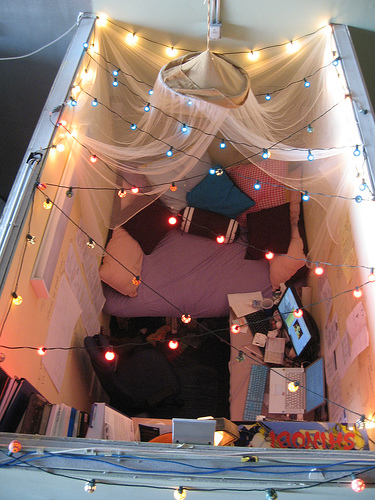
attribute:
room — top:
[17, 221, 337, 477]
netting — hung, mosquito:
[63, 137, 338, 198]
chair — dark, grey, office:
[78, 331, 183, 405]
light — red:
[130, 184, 145, 197]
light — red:
[94, 349, 133, 366]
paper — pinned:
[339, 251, 359, 284]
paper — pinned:
[344, 302, 372, 365]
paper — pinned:
[314, 280, 333, 326]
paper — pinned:
[322, 312, 338, 359]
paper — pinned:
[333, 332, 350, 380]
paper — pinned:
[324, 345, 344, 384]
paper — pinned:
[325, 377, 342, 416]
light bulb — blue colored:
[299, 190, 310, 201]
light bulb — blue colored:
[249, 175, 272, 198]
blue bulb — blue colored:
[218, 136, 232, 150]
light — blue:
[261, 89, 274, 103]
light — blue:
[90, 98, 99, 108]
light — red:
[264, 249, 275, 261]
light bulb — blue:
[249, 176, 268, 199]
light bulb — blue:
[204, 162, 221, 181]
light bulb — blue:
[155, 141, 176, 161]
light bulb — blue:
[257, 88, 275, 105]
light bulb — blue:
[87, 91, 101, 111]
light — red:
[166, 214, 178, 226]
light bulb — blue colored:
[288, 40, 300, 56]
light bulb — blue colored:
[246, 48, 258, 61]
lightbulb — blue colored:
[90, 98, 98, 106]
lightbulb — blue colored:
[179, 123, 187, 133]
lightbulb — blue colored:
[129, 122, 137, 128]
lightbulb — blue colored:
[260, 153, 269, 159]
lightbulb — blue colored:
[303, 149, 315, 161]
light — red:
[180, 195, 266, 272]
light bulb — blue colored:
[210, 167, 215, 175]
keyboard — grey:
[240, 361, 270, 422]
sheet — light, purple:
[102, 227, 312, 321]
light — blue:
[300, 193, 310, 201]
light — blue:
[129, 122, 139, 131]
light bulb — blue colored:
[264, 93, 270, 102]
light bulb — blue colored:
[89, 98, 99, 105]